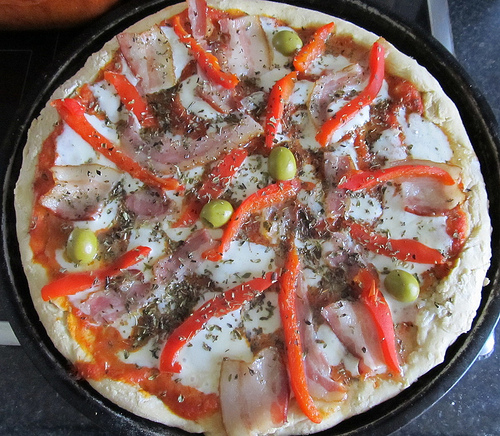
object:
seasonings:
[219, 258, 236, 265]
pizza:
[14, 0, 492, 435]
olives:
[194, 199, 240, 223]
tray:
[0, 0, 500, 435]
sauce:
[30, 121, 68, 279]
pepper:
[353, 262, 401, 373]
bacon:
[297, 272, 347, 391]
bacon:
[217, 343, 289, 435]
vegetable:
[383, 269, 420, 302]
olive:
[65, 230, 107, 270]